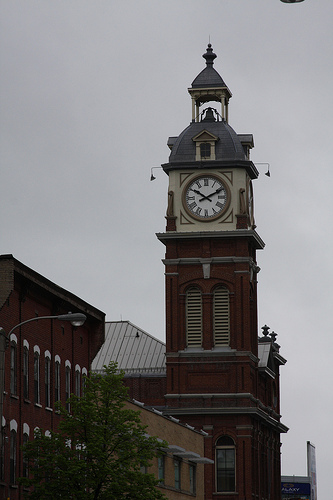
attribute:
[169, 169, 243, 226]
clock — round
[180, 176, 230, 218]
clock — white